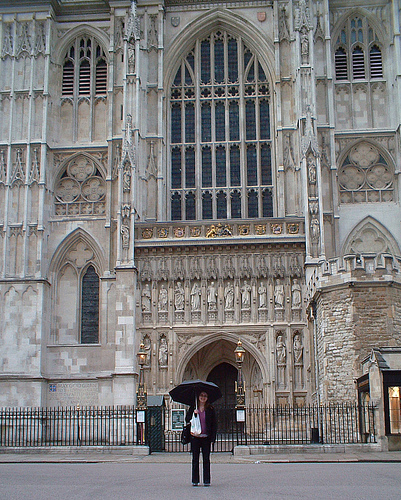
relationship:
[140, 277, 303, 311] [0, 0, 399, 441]
statues on building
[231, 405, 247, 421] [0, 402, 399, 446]
sign on fence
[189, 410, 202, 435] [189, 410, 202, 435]
bag holding bag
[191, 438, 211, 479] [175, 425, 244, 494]
pants on legs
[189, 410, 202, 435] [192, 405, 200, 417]
bag in hand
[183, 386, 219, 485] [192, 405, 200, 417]
woman has hand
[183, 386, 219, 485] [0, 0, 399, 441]
woman in front of building